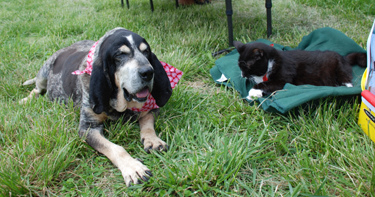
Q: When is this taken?
A: Daytime.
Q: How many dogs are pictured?
A: One.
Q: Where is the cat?
A: On the right of the dog.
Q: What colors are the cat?
A: Black and white.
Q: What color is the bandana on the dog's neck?
A: Red and white.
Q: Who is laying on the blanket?
A: The cat.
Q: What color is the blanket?
A: Green.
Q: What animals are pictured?
A: A dog and a cat.